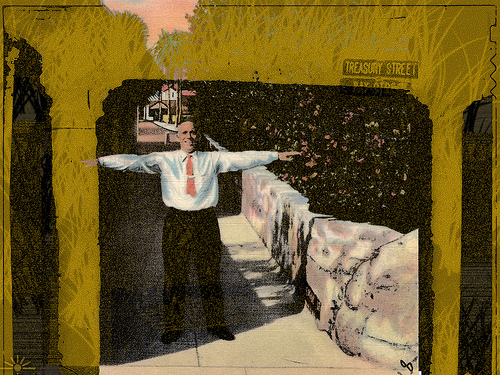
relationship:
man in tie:
[124, 130, 287, 355] [177, 156, 203, 197]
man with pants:
[124, 130, 287, 355] [168, 227, 224, 307]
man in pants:
[124, 130, 287, 355] [168, 227, 224, 307]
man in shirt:
[124, 130, 287, 355] [160, 163, 219, 209]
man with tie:
[124, 130, 287, 355] [177, 156, 203, 197]